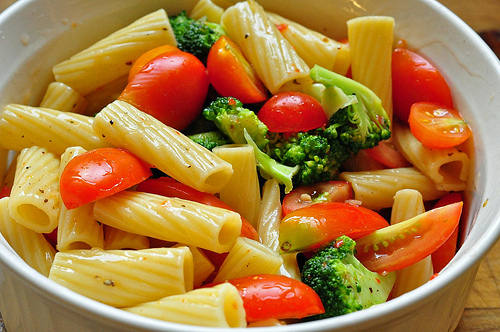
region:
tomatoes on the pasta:
[43, 37, 399, 270]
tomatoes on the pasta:
[63, 40, 347, 253]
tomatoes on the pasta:
[52, 30, 392, 265]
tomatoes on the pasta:
[62, 30, 424, 280]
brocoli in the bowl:
[319, 263, 368, 303]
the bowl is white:
[477, 142, 497, 174]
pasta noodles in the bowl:
[144, 258, 185, 284]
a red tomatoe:
[406, 223, 437, 238]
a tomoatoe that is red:
[78, 163, 121, 183]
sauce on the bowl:
[451, 55, 483, 73]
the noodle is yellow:
[150, 136, 191, 167]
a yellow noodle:
[171, 210, 215, 234]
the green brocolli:
[208, 100, 253, 135]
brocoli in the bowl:
[180, 22, 212, 50]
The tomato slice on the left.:
[60, 152, 152, 204]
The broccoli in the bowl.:
[164, 6, 400, 310]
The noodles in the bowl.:
[0, 12, 453, 316]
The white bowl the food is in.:
[1, 2, 498, 331]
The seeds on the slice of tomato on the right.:
[352, 223, 429, 255]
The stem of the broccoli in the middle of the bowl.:
[240, 131, 300, 193]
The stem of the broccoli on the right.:
[307, 67, 364, 109]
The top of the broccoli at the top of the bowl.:
[168, 5, 210, 60]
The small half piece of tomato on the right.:
[414, 100, 466, 146]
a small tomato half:
[262, 93, 322, 133]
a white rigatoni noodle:
[46, 248, 196, 295]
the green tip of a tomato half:
[280, 223, 317, 251]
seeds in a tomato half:
[423, 108, 462, 136]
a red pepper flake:
[226, 96, 237, 107]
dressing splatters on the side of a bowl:
[15, 17, 77, 65]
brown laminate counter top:
[459, 235, 499, 330]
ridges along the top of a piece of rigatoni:
[103, 105, 230, 176]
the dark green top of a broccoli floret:
[171, 11, 219, 64]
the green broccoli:
[167, 9, 394, 307]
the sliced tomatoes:
[52, 44, 466, 309]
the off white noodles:
[1, 21, 432, 329]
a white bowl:
[0, 1, 497, 331]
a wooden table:
[2, 2, 499, 330]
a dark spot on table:
[478, 19, 499, 62]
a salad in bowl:
[0, 2, 498, 322]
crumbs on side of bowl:
[12, 1, 86, 110]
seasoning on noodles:
[15, 106, 158, 287]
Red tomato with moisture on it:
[257, 88, 330, 137]